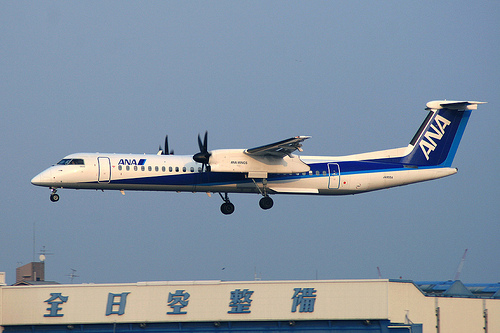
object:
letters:
[37, 282, 332, 321]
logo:
[417, 106, 453, 162]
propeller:
[191, 134, 216, 180]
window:
[56, 156, 85, 168]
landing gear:
[219, 189, 281, 216]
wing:
[212, 135, 315, 178]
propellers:
[153, 134, 178, 159]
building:
[0, 259, 498, 331]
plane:
[30, 99, 490, 216]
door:
[99, 158, 115, 187]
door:
[329, 159, 339, 188]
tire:
[40, 188, 65, 202]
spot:
[339, 177, 352, 187]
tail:
[415, 90, 484, 166]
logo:
[116, 154, 149, 173]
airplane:
[30, 99, 487, 216]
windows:
[116, 164, 194, 174]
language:
[37, 286, 324, 317]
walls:
[219, 156, 314, 179]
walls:
[333, 154, 399, 174]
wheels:
[221, 198, 276, 216]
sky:
[8, 8, 467, 128]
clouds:
[259, 27, 342, 107]